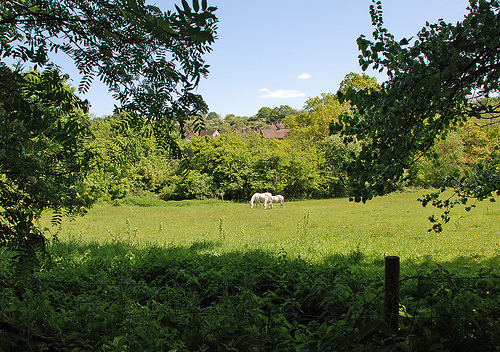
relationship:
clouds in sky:
[249, 68, 311, 109] [0, 1, 499, 119]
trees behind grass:
[2, 0, 500, 257] [29, 197, 498, 266]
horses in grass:
[248, 187, 285, 206] [29, 197, 498, 266]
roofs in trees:
[178, 113, 289, 144] [2, 0, 500, 257]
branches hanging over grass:
[337, 7, 499, 230] [29, 197, 498, 266]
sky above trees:
[0, 1, 499, 119] [2, 0, 500, 257]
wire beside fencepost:
[338, 274, 470, 351] [384, 253, 403, 333]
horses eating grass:
[248, 187, 285, 206] [29, 197, 498, 266]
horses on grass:
[248, 187, 285, 206] [29, 197, 498, 266]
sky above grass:
[0, 1, 499, 119] [29, 197, 498, 266]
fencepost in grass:
[384, 253, 403, 333] [29, 197, 498, 266]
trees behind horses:
[2, 0, 500, 257] [248, 187, 285, 206]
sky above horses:
[0, 1, 499, 119] [248, 187, 285, 206]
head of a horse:
[247, 199, 255, 209] [249, 192, 272, 211]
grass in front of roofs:
[29, 197, 498, 266] [178, 113, 289, 144]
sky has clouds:
[0, 1, 499, 119] [249, 68, 311, 109]